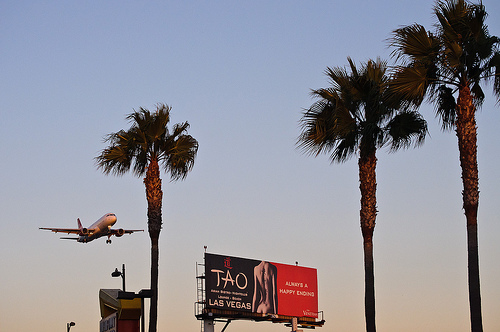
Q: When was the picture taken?
A: Daytime.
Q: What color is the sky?
A: Blue.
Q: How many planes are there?
A: One.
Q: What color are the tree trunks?
A: Brown.